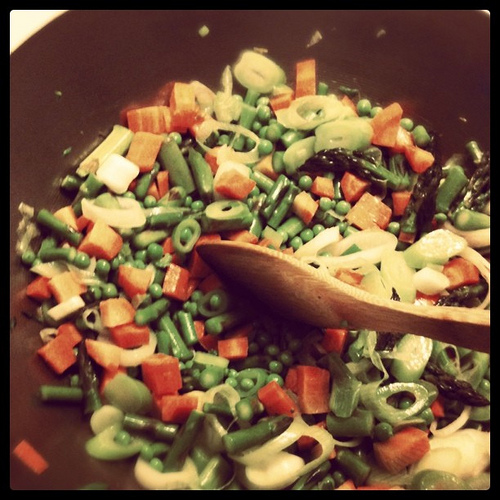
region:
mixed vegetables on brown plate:
[20, 27, 464, 477]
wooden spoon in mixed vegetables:
[111, 202, 486, 369]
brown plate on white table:
[11, 15, 141, 100]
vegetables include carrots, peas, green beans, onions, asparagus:
[55, 74, 427, 498]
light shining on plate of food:
[30, 20, 461, 418]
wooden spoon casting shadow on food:
[180, 171, 387, 363]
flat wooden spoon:
[164, 174, 439, 371]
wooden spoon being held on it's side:
[161, 182, 411, 380]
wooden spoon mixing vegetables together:
[70, 71, 438, 415]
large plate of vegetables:
[4, 57, 485, 431]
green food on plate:
[109, 194, 194, 316]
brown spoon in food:
[238, 244, 468, 351]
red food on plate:
[139, 336, 201, 420]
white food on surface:
[268, 412, 315, 486]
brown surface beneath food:
[32, 405, 80, 465]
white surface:
[16, 14, 48, 38]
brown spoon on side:
[235, 176, 395, 349]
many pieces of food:
[98, 121, 353, 351]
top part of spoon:
[168, 231, 293, 335]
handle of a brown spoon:
[418, 285, 481, 364]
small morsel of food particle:
[194, 22, 218, 38]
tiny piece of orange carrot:
[293, 52, 323, 89]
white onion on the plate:
[98, 151, 140, 188]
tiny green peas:
[70, 249, 110, 271]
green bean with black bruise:
[116, 411, 175, 440]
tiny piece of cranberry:
[306, 146, 372, 172]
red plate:
[39, 45, 154, 117]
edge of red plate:
[20, 37, 64, 78]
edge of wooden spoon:
[190, 230, 254, 303]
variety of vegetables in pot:
[82, 80, 432, 409]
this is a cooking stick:
[206, 240, 491, 360]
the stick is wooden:
[268, 267, 317, 302]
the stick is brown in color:
[327, 292, 372, 316]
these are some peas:
[258, 340, 286, 367]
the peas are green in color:
[262, 340, 289, 366]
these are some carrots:
[277, 365, 336, 417]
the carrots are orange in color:
[299, 372, 325, 411]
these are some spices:
[251, 450, 291, 480]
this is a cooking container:
[49, 24, 136, 80]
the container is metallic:
[93, 24, 150, 74]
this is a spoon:
[261, 265, 311, 294]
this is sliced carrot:
[47, 337, 72, 365]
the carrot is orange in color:
[302, 373, 327, 410]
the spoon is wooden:
[283, 273, 320, 301]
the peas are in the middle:
[132, 242, 162, 262]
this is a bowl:
[89, 23, 145, 85]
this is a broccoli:
[265, 179, 297, 216]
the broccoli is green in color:
[163, 415, 203, 460]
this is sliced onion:
[342, 233, 389, 260]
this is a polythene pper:
[413, 170, 441, 200]